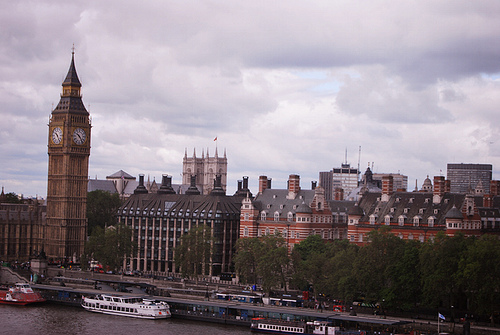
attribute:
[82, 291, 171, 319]
boat — white, floating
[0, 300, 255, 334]
water — dark, rippled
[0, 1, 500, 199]
sky — cloudy, grey, dark, overcast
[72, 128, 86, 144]
clock — white, round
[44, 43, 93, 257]
tower — tall, orange, large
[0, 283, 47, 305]
boat — red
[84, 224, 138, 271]
tree — green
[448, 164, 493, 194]
building — grey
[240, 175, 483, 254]
buildings — similar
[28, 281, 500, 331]
road — busy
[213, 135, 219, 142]
flag — blue